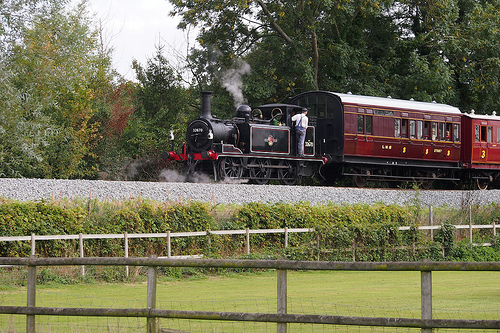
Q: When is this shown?
A: Daytime.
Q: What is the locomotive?
A: Train.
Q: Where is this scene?
A: Countryside.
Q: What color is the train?
A: Red.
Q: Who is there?
A: Conductor.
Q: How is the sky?
A: Overcast.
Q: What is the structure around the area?
A: Fence.